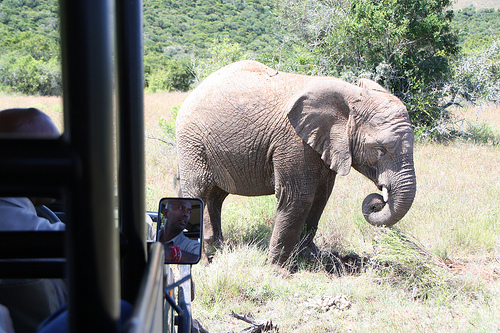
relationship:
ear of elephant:
[287, 83, 353, 176] [172, 59, 417, 270]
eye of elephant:
[372, 146, 386, 156] [172, 59, 417, 270]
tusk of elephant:
[381, 186, 390, 202] [172, 59, 417, 270]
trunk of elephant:
[362, 174, 420, 229] [172, 59, 417, 270]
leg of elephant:
[267, 158, 314, 276] [172, 59, 417, 270]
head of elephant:
[340, 78, 416, 228] [172, 59, 417, 270]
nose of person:
[183, 210, 188, 217] [157, 199, 199, 262]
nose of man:
[183, 210, 188, 217] [157, 199, 199, 262]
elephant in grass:
[172, 59, 417, 270] [0, 90, 499, 332]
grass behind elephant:
[0, 90, 499, 332] [172, 59, 417, 270]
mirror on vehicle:
[155, 197, 204, 265] [0, 0, 204, 332]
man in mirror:
[157, 199, 199, 262] [155, 197, 204, 265]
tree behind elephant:
[320, 0, 451, 137] [172, 59, 417, 270]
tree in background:
[320, 0, 451, 137] [0, 1, 499, 322]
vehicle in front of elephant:
[0, 0, 204, 332] [172, 59, 417, 270]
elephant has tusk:
[172, 59, 417, 270] [381, 186, 390, 202]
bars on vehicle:
[68, 0, 148, 330] [0, 0, 204, 332]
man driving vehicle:
[1, 107, 66, 333] [0, 0, 204, 332]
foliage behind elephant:
[3, 1, 498, 110] [172, 59, 417, 270]